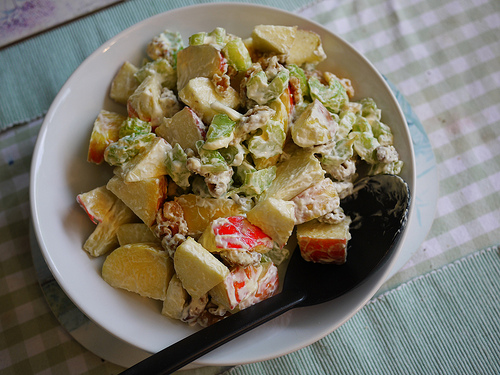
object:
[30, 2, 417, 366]
bowl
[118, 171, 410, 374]
spoon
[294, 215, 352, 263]
apple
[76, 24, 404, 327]
dressing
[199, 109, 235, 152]
food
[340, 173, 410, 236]
dressing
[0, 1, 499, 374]
tablecloth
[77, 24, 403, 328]
assorted vegetables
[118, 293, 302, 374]
handle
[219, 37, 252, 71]
grape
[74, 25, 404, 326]
apple salad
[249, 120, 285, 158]
celery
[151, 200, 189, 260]
pecan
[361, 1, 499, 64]
stripe